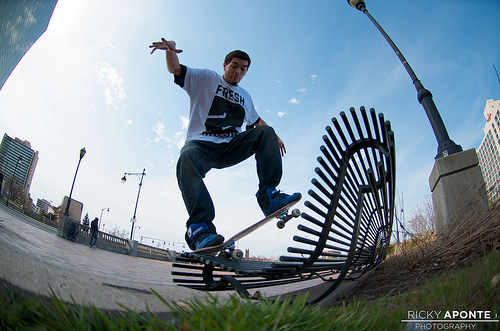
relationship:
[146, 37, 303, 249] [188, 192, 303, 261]
man on skateboard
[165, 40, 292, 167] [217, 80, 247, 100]
shirt with writing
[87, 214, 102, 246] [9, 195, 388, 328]
person on sidewalk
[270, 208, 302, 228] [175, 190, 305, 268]
wheels on skateboard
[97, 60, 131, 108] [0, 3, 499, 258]
cloud in sky